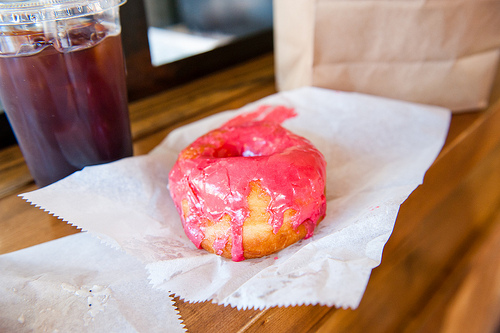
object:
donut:
[162, 122, 327, 264]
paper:
[18, 87, 455, 316]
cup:
[2, 2, 137, 187]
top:
[2, 2, 129, 27]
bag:
[270, 2, 499, 113]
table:
[0, 50, 499, 332]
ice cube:
[61, 24, 99, 49]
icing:
[172, 119, 327, 258]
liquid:
[2, 32, 134, 185]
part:
[248, 214, 270, 241]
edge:
[231, 299, 315, 318]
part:
[346, 123, 382, 157]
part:
[444, 194, 463, 252]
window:
[123, 0, 273, 98]